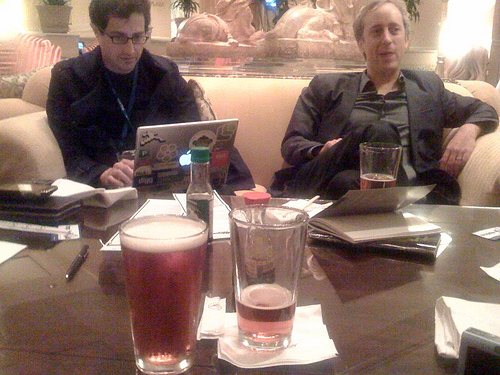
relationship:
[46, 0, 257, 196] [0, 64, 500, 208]
man on couch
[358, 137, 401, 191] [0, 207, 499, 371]
drink on table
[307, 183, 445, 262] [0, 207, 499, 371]
books on table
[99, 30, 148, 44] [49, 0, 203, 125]
eyeglasses on man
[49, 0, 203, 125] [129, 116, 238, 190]
man looking at laptop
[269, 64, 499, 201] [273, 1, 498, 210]
clothes on man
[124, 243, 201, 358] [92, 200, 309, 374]
beverage in glasses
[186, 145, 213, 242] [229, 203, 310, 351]
condiment bottle behind glass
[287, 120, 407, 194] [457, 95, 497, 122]
legs by elbow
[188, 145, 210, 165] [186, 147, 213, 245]
green cap on condiment bottle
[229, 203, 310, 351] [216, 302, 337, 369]
glass on napkin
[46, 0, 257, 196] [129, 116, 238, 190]
man looking at laptop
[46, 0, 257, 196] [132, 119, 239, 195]
man on laptop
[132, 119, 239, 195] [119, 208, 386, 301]
laptop on table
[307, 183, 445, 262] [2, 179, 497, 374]
books on table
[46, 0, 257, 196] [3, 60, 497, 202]
man on couch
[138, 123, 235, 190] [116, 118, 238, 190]
stickers on laptop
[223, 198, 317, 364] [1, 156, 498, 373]
glass on table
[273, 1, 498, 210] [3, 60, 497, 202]
man sitting on couch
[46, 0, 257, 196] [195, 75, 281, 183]
man sitting on couch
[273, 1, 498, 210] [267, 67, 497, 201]
man wearing jacket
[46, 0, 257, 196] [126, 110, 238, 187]
man looking at laptop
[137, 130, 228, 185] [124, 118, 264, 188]
stickers on lid of laptop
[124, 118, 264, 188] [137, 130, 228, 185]
laptop with stickers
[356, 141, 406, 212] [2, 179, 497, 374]
glass sitting on table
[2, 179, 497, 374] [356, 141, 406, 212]
table with glass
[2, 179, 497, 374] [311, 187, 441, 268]
table with books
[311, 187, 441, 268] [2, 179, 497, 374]
books on table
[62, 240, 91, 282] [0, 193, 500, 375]
pen on table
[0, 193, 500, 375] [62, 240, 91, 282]
table with a pen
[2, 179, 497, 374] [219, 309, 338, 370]
table with a napkin